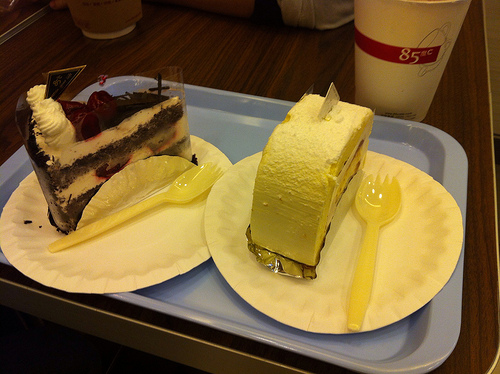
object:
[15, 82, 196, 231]
cake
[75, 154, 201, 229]
paper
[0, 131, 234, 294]
plate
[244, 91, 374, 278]
cake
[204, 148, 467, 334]
plate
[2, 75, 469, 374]
tray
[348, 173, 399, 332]
utensil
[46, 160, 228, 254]
utensil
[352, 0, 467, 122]
cup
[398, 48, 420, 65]
number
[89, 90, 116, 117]
cherry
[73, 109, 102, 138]
cherry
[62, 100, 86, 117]
cherry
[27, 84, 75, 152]
topping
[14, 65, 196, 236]
wrapper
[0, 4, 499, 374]
table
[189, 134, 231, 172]
edge